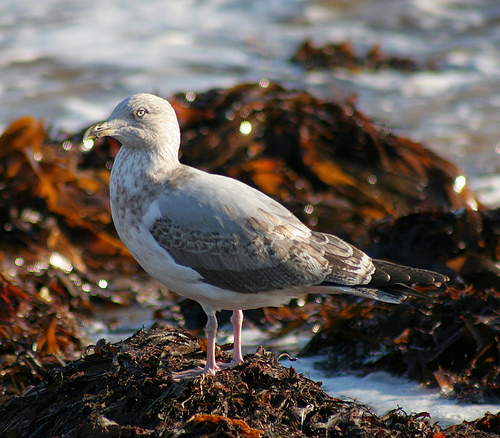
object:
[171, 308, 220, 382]
legs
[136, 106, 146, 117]
eye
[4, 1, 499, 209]
river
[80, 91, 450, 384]
pigeon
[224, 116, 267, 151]
leaves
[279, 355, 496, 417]
foam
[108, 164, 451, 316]
feathers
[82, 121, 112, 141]
beak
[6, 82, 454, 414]
surface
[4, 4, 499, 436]
photo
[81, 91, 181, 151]
head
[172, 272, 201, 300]
white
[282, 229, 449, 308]
bird's tail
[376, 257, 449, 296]
black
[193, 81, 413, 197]
pile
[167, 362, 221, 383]
feet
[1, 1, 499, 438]
background